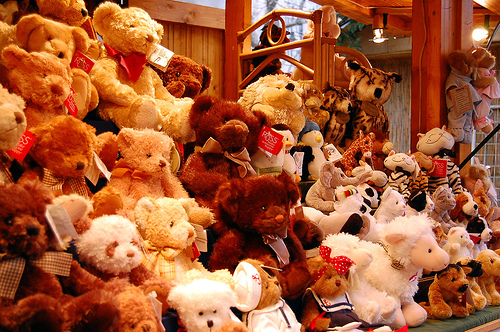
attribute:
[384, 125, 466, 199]
cats — stuffed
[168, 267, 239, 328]
teddy bear — white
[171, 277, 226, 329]
teddy bear — beautiful, white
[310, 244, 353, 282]
bow — red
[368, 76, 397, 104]
teddy — brown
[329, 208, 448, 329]
bear — white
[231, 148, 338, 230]
bear — brown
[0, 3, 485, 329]
teddy bear — brown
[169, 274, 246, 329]
bear — white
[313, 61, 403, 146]
stuffed owl — spotted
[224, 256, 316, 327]
bear — toy, dressed as sailor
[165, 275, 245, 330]
teddy bear — white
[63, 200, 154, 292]
panda — stuffed, toy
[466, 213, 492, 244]
toy dog — black, white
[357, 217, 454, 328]
teddy bear — big, white, sheep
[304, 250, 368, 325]
bear — toy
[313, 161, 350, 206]
elephant — small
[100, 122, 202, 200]
bear — light, brown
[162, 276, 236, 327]
teddy bear — white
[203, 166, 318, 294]
bear — large, brown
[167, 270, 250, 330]
animal — stuffed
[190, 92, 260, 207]
animal — stuffed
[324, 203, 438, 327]
animal — stuffed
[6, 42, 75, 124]
animal — stuffed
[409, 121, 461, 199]
animal — stuffed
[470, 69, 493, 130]
outfit — pink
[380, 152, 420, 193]
cat — stuffed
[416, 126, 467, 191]
cat — stuffed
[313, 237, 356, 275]
bow — polka-dot